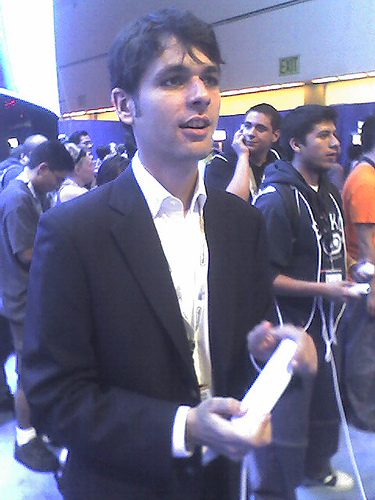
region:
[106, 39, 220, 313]
person in the crowd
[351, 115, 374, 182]
person in the crowd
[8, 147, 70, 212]
person in the crowd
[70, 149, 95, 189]
person in the crowd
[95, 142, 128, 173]
person in the crowd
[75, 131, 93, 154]
person in the crowd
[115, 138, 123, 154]
person in the crowd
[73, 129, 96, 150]
person in the crowd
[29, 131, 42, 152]
person in the crowd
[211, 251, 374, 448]
people holding wii controllers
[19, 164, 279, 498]
a man wears a black suit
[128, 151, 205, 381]
a white dress shirt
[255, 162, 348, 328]
a black hoodie with white lettering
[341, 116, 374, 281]
a man wears an orange t-shirt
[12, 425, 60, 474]
a white sock worn with a black shoe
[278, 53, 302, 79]
an exit sign mounted high on a wall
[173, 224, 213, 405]
a white and black neck strap holding a card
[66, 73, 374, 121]
a yellow area on the wall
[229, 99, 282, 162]
a man talks on a cell phone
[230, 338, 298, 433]
The man is holding a wii controller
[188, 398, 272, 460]
The right hand of the man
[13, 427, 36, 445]
The man is wearing white socks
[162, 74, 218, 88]
The eyes of the man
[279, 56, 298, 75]
An Exit sign in the room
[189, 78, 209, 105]
The nose of the man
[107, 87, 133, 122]
The right ear of the man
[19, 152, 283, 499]
The man is wearing a suit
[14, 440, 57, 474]
The man is wearing black shoes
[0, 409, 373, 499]
The ground beneath the people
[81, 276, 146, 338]
a man is wearing a black jacket.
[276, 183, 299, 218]
a black strap to a black back pack.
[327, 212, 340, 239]
a man is wearing a blue and white shirt.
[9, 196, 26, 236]
a man is wearing a blue tea shirt.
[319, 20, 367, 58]
a dark color white wall.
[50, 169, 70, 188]
a man is wearing glasses.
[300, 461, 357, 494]
a man is wearing a black and white sneaker.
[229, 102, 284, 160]
a man is talking on a cell phone.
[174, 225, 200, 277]
a man is wearing a white shirt.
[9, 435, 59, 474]
a man is wearing a pair of black sneakers.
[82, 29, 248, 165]
the head of a man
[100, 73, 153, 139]
the ear of a man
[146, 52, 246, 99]
the eyes of a man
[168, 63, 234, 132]
the nose of a man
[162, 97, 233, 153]
the lips of a man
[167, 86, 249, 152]
the mouth of a man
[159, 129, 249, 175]
the chin of a man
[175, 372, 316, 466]
the hand of a man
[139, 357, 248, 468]
the wrist of a man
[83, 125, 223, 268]
the neck of a man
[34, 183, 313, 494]
black jacket worn by man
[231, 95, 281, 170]
cell phone held to ear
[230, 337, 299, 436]
a rectangular Wii remote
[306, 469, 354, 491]
a black and white shoe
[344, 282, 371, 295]
a white colored Wii remote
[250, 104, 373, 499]
a man with black hair and a black jacket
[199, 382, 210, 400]
a white name tag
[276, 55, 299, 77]
an Exit sound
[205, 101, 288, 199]
a man talking on a cellphone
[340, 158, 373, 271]
an orange colored shirt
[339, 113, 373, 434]
a person with black hair wearing an orange shirt